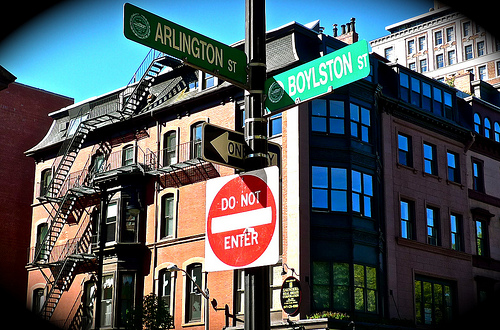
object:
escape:
[27, 101, 119, 202]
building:
[22, 2, 500, 329]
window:
[311, 163, 332, 190]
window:
[422, 144, 440, 162]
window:
[327, 97, 347, 118]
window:
[349, 100, 362, 124]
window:
[309, 186, 332, 210]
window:
[327, 188, 349, 214]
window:
[351, 189, 366, 215]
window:
[360, 191, 377, 217]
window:
[400, 217, 417, 241]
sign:
[200, 163, 287, 274]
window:
[398, 199, 412, 221]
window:
[423, 205, 441, 228]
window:
[450, 212, 463, 235]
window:
[422, 157, 440, 175]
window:
[443, 165, 464, 185]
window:
[444, 148, 459, 168]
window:
[364, 263, 379, 291]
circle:
[204, 174, 278, 267]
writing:
[216, 187, 266, 214]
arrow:
[206, 130, 280, 170]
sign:
[196, 119, 291, 178]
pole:
[241, 0, 278, 329]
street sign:
[260, 33, 375, 118]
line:
[207, 203, 283, 237]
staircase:
[118, 47, 181, 113]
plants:
[305, 306, 345, 318]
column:
[285, 305, 352, 325]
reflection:
[314, 258, 382, 314]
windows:
[329, 284, 355, 311]